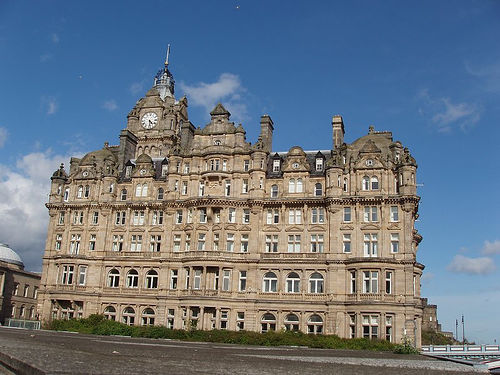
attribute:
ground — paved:
[34, 328, 159, 371]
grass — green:
[105, 316, 223, 340]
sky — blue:
[406, 71, 496, 248]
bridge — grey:
[415, 325, 497, 359]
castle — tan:
[45, 104, 431, 373]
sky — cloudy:
[396, 201, 498, 313]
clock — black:
[124, 103, 194, 153]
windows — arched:
[95, 245, 368, 337]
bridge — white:
[424, 341, 489, 360]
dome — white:
[0, 245, 39, 266]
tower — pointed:
[144, 31, 179, 103]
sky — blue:
[188, 83, 428, 126]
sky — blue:
[231, 11, 442, 85]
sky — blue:
[409, 86, 474, 213]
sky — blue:
[12, 21, 140, 136]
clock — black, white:
[126, 94, 219, 158]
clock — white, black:
[119, 93, 170, 141]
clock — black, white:
[126, 112, 174, 142]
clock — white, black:
[134, 113, 187, 158]